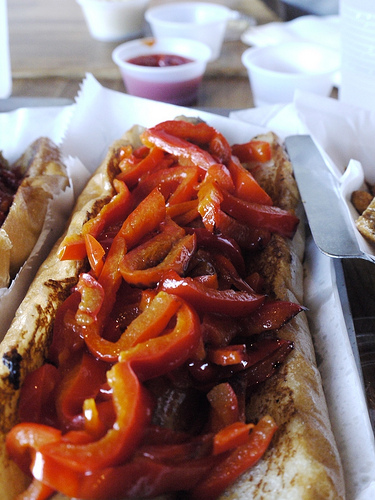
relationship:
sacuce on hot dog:
[151, 349, 253, 425] [0, 106, 312, 498]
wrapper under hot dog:
[55, 77, 132, 162] [11, 98, 326, 465]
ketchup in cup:
[145, 55, 171, 65] [184, 38, 209, 70]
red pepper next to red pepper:
[72, 247, 218, 403] [113, 175, 194, 273]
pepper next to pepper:
[189, 387, 300, 464] [130, 461, 208, 492]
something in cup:
[172, 0, 207, 27] [73, 3, 156, 41]